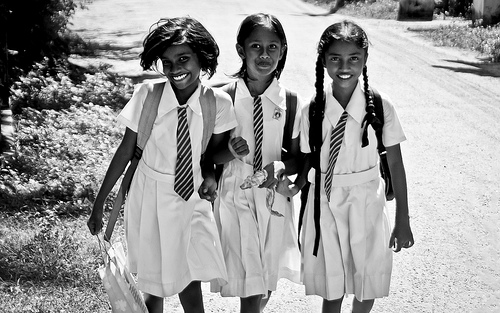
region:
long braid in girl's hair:
[310, 40, 330, 188]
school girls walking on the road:
[118, 11, 418, 268]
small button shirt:
[268, 101, 290, 126]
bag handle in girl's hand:
[76, 212, 138, 271]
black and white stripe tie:
[238, 93, 280, 183]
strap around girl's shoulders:
[361, 83, 399, 140]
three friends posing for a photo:
[77, 20, 447, 311]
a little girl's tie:
[161, 102, 215, 214]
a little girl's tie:
[247, 93, 274, 215]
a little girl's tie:
[308, 102, 353, 230]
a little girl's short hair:
[132, 10, 222, 76]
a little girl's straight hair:
[225, 13, 295, 100]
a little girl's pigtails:
[307, 41, 399, 143]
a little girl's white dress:
[302, 77, 412, 310]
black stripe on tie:
[176, 105, 183, 115]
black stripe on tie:
[178, 108, 185, 118]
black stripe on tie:
[175, 115, 185, 128]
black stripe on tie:
[174, 123, 188, 138]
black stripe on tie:
[175, 130, 190, 155]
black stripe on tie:
[176, 150, 192, 172]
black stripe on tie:
[174, 164, 191, 189]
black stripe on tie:
[176, 164, 193, 193]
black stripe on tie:
[182, 184, 192, 200]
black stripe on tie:
[184, 188, 194, 201]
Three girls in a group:
[77, 17, 423, 305]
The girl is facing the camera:
[130, 5, 223, 105]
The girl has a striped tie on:
[168, 103, 201, 206]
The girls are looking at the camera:
[110, 5, 395, 190]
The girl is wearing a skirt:
[123, 160, 228, 300]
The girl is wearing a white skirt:
[119, 159, 228, 302]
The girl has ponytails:
[312, 20, 382, 150]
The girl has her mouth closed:
[231, 8, 291, 86]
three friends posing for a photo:
[93, 19, 486, 296]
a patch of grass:
[0, 40, 106, 302]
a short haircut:
[130, 16, 217, 78]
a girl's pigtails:
[300, 10, 392, 139]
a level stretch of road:
[111, 3, 489, 295]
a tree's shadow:
[425, 43, 497, 87]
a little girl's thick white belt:
[295, 163, 411, 203]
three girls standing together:
[90, 6, 418, 311]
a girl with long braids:
[355, 55, 375, 150]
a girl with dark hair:
[230, 15, 291, 80]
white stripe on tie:
[178, 108, 185, 116]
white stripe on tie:
[175, 114, 189, 129]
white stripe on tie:
[174, 128, 189, 147]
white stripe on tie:
[175, 134, 191, 156]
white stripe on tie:
[173, 163, 190, 191]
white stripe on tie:
[181, 186, 194, 198]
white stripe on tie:
[252, 103, 262, 121]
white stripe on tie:
[252, 115, 262, 132]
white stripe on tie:
[328, 130, 341, 147]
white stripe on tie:
[330, 127, 344, 138]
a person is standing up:
[78, 17, 222, 304]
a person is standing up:
[225, 2, 299, 310]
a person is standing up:
[299, 22, 403, 306]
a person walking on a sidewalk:
[89, 12, 214, 311]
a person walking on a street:
[221, 11, 288, 308]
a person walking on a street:
[293, 16, 412, 311]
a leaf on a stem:
[100, 103, 111, 123]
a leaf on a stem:
[70, 102, 83, 117]